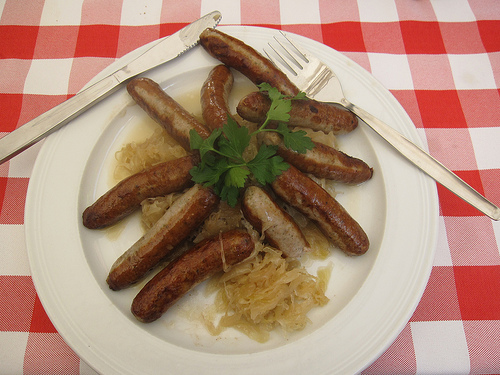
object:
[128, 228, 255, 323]
sausage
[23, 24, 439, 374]
plate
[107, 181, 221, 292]
sausage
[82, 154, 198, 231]
sausage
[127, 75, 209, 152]
sausage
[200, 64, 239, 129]
sausage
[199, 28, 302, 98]
sausage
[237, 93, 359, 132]
sausage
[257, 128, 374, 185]
sausage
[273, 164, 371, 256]
sausage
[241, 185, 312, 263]
sausage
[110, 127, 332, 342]
sauerkraut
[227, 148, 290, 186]
sprig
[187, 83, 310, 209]
parsley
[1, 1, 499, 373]
tablecloth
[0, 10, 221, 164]
knife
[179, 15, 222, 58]
edge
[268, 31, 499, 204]
fork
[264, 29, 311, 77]
tines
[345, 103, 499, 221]
handle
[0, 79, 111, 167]
handle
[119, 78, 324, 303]
food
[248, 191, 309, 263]
bite